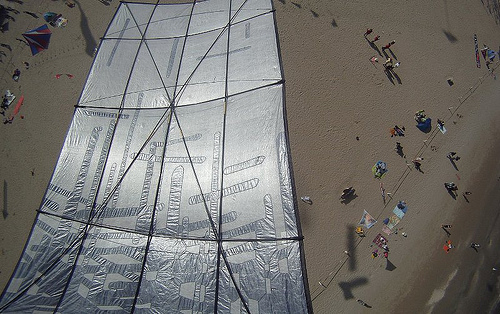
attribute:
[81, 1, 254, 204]
kite — large, edge, suspended, colored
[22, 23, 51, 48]
tent — red, air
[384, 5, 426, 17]
sand — brown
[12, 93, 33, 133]
flag — red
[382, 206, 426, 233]
sign — white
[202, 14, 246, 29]
ropes — black, intersecting